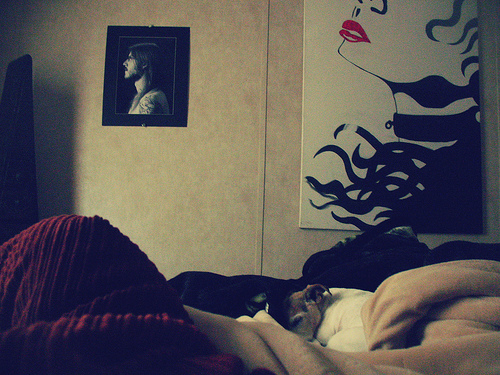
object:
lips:
[339, 19, 371, 43]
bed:
[0, 213, 499, 374]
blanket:
[181, 258, 499, 374]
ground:
[240, 87, 285, 151]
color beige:
[395, 277, 440, 337]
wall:
[0, 0, 500, 282]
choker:
[385, 106, 481, 143]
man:
[123, 42, 171, 115]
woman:
[303, 0, 485, 232]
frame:
[101, 25, 192, 128]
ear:
[142, 61, 148, 69]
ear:
[302, 283, 333, 302]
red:
[37, 250, 122, 337]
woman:
[302, 0, 486, 237]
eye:
[292, 315, 303, 326]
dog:
[284, 282, 378, 355]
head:
[283, 284, 333, 341]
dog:
[165, 270, 316, 329]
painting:
[299, 0, 487, 236]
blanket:
[0, 214, 278, 374]